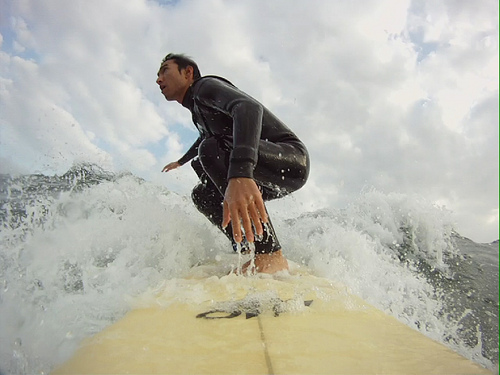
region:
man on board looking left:
[147, 50, 207, 112]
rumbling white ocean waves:
[5, 165, 195, 277]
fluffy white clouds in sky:
[307, 5, 482, 146]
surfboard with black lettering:
[147, 281, 367, 341]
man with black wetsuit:
[142, 45, 302, 275]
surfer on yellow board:
[155, 50, 328, 370]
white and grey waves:
[327, 192, 495, 304]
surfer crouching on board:
[151, 50, 311, 366]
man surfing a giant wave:
[135, 31, 336, 371]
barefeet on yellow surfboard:
[175, 186, 334, 326]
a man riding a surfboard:
[156, 50, 310, 277]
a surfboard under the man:
[41, 247, 488, 372]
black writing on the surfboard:
[194, 295, 314, 320]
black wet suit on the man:
[179, 73, 311, 257]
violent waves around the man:
[0, 158, 490, 366]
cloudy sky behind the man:
[0, 0, 497, 242]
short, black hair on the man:
[159, 52, 199, 83]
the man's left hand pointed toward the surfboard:
[219, 178, 266, 241]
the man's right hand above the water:
[159, 159, 181, 174]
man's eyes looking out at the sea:
[157, 67, 169, 77]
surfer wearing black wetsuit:
[136, 60, 326, 263]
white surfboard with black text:
[91, 256, 445, 374]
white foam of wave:
[15, 172, 435, 364]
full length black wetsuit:
[174, 83, 304, 253]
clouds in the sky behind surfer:
[17, 11, 483, 203]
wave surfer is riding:
[12, 161, 497, 361]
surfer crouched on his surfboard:
[87, 59, 487, 369]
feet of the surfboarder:
[217, 240, 289, 282]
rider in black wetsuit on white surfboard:
[65, 44, 452, 374]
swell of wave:
[32, 186, 484, 374]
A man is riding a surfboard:
[60, 26, 443, 326]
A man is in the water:
[57, 18, 472, 339]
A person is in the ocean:
[46, 35, 462, 345]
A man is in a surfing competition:
[33, 20, 464, 330]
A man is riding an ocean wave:
[63, 30, 468, 346]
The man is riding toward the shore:
[70, 27, 466, 332]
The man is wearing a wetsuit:
[55, 33, 443, 331]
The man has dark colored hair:
[72, 15, 437, 310]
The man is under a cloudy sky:
[8, 11, 478, 336]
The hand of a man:
[224, 189, 262, 241]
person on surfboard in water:
[127, 50, 335, 288]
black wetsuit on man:
[165, 95, 317, 247]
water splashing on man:
[114, 280, 141, 304]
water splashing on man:
[376, 253, 415, 279]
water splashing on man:
[393, 295, 425, 315]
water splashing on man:
[375, 221, 403, 248]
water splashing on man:
[43, 314, 60, 334]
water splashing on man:
[105, 205, 135, 224]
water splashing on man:
[131, 193, 152, 216]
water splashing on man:
[183, 280, 209, 297]